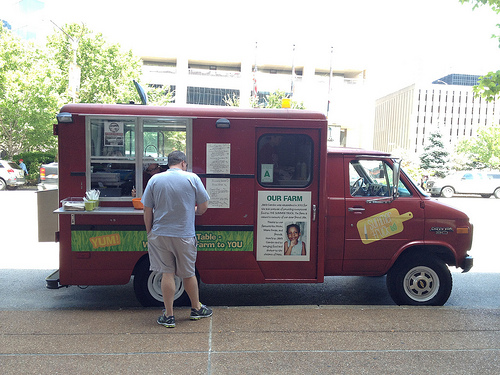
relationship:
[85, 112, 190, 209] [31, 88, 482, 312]
window on mobile kitchen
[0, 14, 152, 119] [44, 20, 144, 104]
sun on tree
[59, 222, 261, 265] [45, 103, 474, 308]
green sign on mobile kitchen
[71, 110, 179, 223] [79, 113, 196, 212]
grey frame on window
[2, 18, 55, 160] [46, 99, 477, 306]
tree behind truck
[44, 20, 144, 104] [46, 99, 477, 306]
tree behind truck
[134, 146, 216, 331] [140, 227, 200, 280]
man has pants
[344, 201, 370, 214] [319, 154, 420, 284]
handle on door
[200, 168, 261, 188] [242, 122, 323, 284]
handle on door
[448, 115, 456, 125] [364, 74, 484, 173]
window on building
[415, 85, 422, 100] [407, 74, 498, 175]
window on building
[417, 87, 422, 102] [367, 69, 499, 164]
window on building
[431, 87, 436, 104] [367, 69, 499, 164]
window on building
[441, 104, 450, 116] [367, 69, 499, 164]
window on building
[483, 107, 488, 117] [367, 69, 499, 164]
window on building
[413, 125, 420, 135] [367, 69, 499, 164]
window on building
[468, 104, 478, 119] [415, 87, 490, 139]
window on building